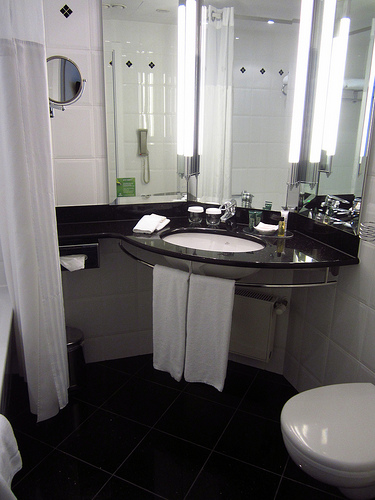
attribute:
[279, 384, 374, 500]
toilet — all white, white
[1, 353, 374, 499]
floor — black, tile, dark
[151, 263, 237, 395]
towels — large, small, white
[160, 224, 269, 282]
sink — white, used with water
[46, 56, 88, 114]
mirror — round, small, circular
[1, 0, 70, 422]
curtain — white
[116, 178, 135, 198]
sticker — green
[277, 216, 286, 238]
bottle oil — yellow, small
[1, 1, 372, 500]
bathroom — black, white, clean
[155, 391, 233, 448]
tile — black, large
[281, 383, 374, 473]
toilet seat — down, white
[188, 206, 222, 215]
covers — white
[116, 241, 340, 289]
bar — metal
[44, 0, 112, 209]
wall — tile